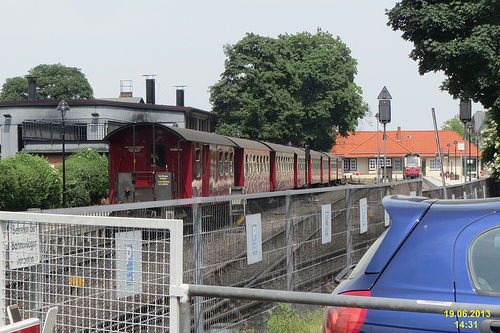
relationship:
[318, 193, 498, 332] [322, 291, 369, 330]
car has tail light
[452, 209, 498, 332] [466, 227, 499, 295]
door has window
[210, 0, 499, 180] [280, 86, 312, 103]
tree has leaves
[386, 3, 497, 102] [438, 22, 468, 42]
tree has leaves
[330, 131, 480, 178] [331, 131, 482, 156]
building has roof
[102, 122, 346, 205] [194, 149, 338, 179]
car has window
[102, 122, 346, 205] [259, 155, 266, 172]
car has window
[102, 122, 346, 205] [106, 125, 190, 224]
car has back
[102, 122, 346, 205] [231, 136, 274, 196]
car has car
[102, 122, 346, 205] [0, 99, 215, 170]
car passing house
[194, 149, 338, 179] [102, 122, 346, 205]
window on car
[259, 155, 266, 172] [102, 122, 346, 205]
window on car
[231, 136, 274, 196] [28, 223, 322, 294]
car on tracks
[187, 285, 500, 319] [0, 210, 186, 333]
railing attached to fence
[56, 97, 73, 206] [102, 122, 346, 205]
street light next to car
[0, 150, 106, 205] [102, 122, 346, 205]
bushes next to car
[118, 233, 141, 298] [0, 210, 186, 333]
sign on fence